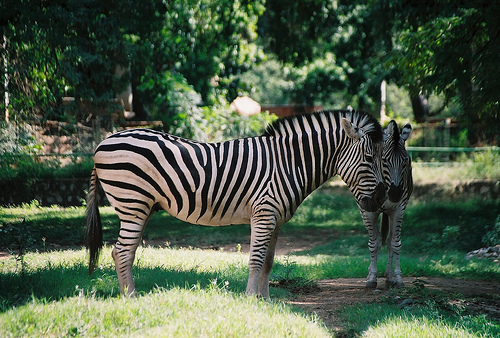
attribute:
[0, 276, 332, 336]
spot — sunny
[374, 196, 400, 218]
nose — dark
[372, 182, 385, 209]
nose — black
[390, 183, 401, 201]
nose — black